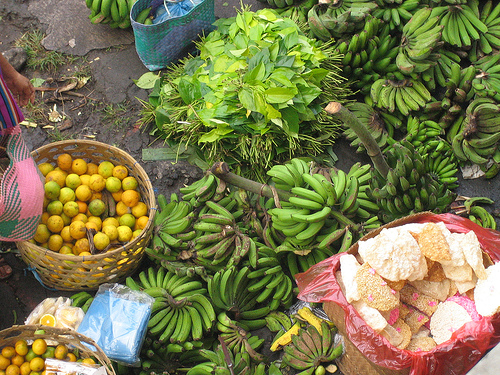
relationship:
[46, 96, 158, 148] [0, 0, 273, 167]
dirt under grass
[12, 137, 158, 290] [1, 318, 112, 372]
basket full of basket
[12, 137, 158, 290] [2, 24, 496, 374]
basket full of fruit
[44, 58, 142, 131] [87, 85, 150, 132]
muddy ground with grass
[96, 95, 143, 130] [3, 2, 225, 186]
grass on ground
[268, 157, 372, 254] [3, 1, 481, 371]
bananas on ground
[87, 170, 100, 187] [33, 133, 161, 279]
fruit in basket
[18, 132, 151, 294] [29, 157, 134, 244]
basket of lemons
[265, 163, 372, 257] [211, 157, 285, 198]
bananas on branch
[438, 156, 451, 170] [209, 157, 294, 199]
banana on branch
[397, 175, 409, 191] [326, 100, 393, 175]
banana on branch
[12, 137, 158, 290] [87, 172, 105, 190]
basket of fruit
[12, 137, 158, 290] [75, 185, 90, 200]
basket of fruit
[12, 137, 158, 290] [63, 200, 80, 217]
basket of fruit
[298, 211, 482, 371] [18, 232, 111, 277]
bag lining basket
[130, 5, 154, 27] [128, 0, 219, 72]
bananas inside bag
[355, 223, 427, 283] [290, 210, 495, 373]
bread in basket